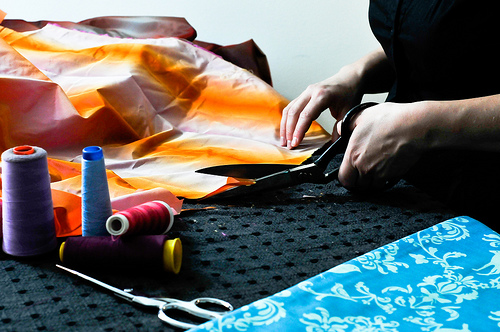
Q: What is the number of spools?
A: Four.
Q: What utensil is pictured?
A: Scissors.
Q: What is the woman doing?
A: Cutting fabric.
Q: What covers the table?
A: A black material.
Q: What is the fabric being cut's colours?
A: Orange and white.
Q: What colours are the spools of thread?
A: Purple, red, blue and magenta.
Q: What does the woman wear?
A: Black shirt.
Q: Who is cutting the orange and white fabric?
A: A woman.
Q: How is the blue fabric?
A: Has white pattern.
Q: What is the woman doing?
A: Cutting the orange fabric.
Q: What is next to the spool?
A: Scissors.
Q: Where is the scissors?
A: Lying on the cloth.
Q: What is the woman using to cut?
A: A pair of scissors.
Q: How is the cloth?
A: Blue with white design.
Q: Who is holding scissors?
A: A woman.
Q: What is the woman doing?
A: Cutting fabric.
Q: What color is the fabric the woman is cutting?
A: Orange and white.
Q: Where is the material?
A: On the table.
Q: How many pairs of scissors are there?
A: Two.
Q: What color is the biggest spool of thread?
A: Purple.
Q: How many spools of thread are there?
A: Four.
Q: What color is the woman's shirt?
A: Black.